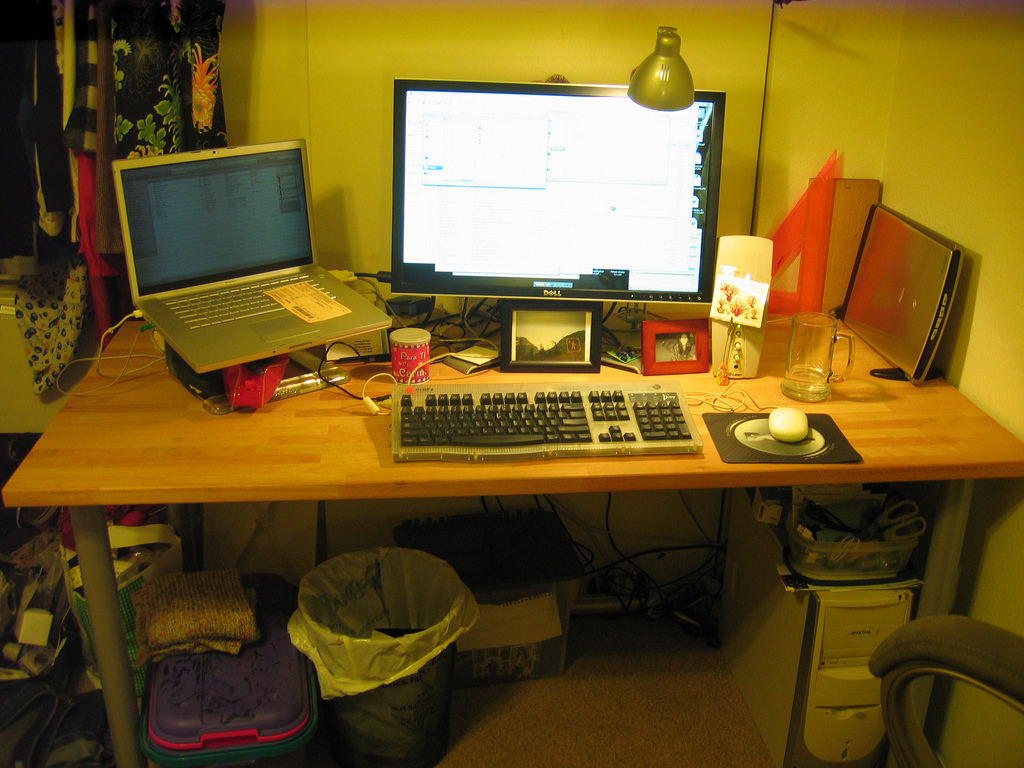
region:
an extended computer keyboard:
[391, 377, 704, 461]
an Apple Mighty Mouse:
[768, 403, 810, 439]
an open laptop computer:
[111, 134, 393, 373]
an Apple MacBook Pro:
[108, 138, 394, 376]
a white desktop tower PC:
[716, 491, 919, 766]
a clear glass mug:
[783, 308, 859, 398]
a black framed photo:
[498, 298, 598, 372]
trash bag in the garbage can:
[283, 545, 486, 757]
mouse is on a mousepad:
[696, 398, 870, 471]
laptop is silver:
[89, 127, 404, 384]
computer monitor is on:
[388, 71, 746, 316]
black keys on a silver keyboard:
[377, 374, 703, 467]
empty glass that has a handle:
[782, 303, 859, 403]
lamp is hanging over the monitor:
[608, 8, 723, 123]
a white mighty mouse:
[760, 375, 818, 462]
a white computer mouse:
[757, 388, 819, 455]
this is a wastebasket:
[267, 540, 495, 765]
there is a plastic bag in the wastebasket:
[289, 527, 492, 761]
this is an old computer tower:
[710, 500, 908, 766]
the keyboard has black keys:
[349, 345, 735, 501]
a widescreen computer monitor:
[340, 51, 756, 327]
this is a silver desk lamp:
[612, 13, 720, 137]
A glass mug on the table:
[784, 310, 849, 400]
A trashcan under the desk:
[289, 558, 486, 764]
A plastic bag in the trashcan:
[289, 544, 474, 694]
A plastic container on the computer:
[788, 495, 909, 584]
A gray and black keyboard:
[390, 383, 698, 457]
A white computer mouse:
[768, 403, 806, 438]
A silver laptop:
[114, 137, 387, 379]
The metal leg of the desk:
[65, 509, 152, 766]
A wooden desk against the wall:
[0, 292, 1021, 758]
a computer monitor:
[391, 77, 723, 311]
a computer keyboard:
[391, 383, 698, 456]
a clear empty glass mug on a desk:
[782, 311, 853, 398]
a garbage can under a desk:
[303, 545, 463, 765]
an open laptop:
[113, 137, 393, 382]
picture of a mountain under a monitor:
[501, 304, 596, 369]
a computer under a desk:
[700, 488, 917, 765]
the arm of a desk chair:
[866, 620, 1018, 766]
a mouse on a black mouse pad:
[771, 400, 810, 443]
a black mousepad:
[706, 410, 859, 465]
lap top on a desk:
[101, 125, 397, 379]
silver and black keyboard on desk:
[379, 377, 705, 461]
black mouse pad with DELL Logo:
[699, 404, 867, 471]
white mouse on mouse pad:
[765, 404, 811, 444]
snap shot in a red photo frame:
[638, 314, 712, 378]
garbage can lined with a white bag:
[293, 538, 480, 766]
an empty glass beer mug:
[775, 306, 859, 406]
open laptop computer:
[105, 133, 397, 372]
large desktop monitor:
[382, 69, 733, 322]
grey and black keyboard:
[388, 369, 708, 461]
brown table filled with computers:
[3, 301, 1018, 764]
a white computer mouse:
[761, 402, 816, 442]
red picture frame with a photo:
[632, 313, 718, 375]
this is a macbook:
[75, 110, 404, 401]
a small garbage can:
[274, 531, 468, 766]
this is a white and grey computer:
[739, 515, 908, 763]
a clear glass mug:
[778, 303, 867, 401]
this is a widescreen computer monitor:
[363, 53, 766, 323]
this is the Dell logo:
[536, 287, 568, 298]